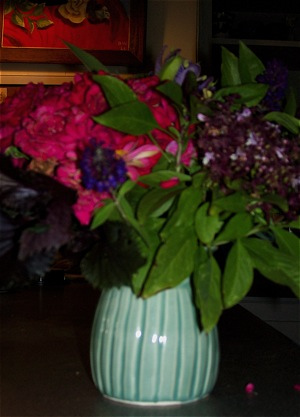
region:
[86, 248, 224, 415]
the vase is green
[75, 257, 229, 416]
lines on the vase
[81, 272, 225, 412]
light shining on the vase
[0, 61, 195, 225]
the flowers are pink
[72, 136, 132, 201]
the flower is purple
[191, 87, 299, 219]
the flowers are purple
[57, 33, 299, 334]
flower leaves are green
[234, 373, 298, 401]
pink flower on table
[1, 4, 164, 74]
picture framed on wall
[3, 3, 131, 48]
background of picture is red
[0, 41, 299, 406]
plant in a vase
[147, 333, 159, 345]
light glare on the vase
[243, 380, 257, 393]
pink petal that has fallen off the plant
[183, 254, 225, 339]
green leaf hanging over the side of the vase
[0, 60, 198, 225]
a bouquet of pink flowers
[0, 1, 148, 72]
artwork hanging on the wall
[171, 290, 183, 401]
thin line on the vase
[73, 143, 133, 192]
blue flower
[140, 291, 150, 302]
pointy tip of the flower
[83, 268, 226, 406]
white vase on the table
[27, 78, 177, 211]
the flowers are red in color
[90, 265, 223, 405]
the vase is made of ceramic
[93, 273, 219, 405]
the vase is shiny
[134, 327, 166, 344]
highlights are in the vase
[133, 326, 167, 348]
the highlights are white in color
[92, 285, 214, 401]
bands are in the vase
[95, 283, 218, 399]
the bands are green in color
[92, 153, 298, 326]
the leaves are green in color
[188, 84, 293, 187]
the flowers are purple in color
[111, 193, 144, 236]
the flower is on a stem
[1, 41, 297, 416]
this vase of flowers are sadly out of focus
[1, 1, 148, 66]
the picture of flowers is in better focus than the real flowers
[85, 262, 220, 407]
the flower vase is a pale blue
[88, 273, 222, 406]
the flower vase is ceramic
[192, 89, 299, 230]
purple flowers are part of this arrangement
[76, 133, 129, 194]
blue-violet flowers are part of this arrangement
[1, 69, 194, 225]
vivid pink flowers are part of this arrangement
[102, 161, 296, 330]
these leaves are big and green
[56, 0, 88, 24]
a yellow flower is part of the painting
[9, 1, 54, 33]
yellowish green leaves are part of the painting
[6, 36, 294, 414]
bright flowers in a green vase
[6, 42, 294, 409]
flowers and greenery in a green vase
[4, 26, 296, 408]
bright flowers in a striped jade colored vase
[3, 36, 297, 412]
hand arranged flowers in green vase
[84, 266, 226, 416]
green striped vase with glaze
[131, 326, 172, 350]
reflection of light in green vase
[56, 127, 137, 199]
purple flower next to pink flowers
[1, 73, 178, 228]
collection of bright pink flowers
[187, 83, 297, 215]
collection of purple flowers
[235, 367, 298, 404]
fallen pink petals on table